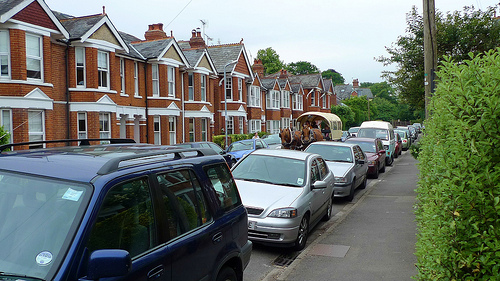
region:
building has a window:
[74, 46, 85, 86]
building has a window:
[95, 50, 107, 88]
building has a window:
[26, 33, 42, 78]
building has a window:
[166, 66, 175, 97]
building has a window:
[186, 70, 193, 100]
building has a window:
[79, 112, 89, 144]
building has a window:
[166, 116, 178, 142]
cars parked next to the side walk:
[3, 120, 437, 279]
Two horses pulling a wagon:
[277, 105, 342, 155]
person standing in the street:
[250, 125, 265, 150]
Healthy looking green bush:
[415, 45, 495, 276]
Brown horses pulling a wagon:
[277, 108, 342, 149]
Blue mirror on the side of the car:
[80, 243, 139, 279]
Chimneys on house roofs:
[131, 20, 211, 72]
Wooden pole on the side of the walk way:
[421, 0, 443, 130]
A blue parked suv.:
[0, 138, 254, 280]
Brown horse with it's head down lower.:
[278, 125, 300, 148]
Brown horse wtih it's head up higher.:
[297, 123, 324, 148]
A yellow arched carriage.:
[292, 111, 342, 143]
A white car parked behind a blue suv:
[226, 147, 336, 251]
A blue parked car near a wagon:
[226, 140, 267, 161]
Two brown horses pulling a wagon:
[277, 123, 323, 150]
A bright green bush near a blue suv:
[420, 55, 499, 278]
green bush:
[451, 85, 488, 210]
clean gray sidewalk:
[371, 193, 391, 262]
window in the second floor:
[70, 48, 91, 93]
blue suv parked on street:
[28, 154, 241, 263]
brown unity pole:
[410, 6, 460, 116]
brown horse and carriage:
[291, 113, 351, 143]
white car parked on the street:
[226, 141, 330, 263]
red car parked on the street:
[344, 133, 388, 171]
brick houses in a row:
[66, 37, 301, 144]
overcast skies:
[276, 8, 375, 60]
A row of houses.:
[7, 1, 358, 132]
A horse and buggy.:
[280, 97, 350, 147]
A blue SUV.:
[5, 130, 251, 275]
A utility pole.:
[407, 1, 457, 101]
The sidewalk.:
[340, 135, 420, 272]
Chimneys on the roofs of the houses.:
[136, 15, 291, 75]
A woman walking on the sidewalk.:
[245, 120, 260, 140]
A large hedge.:
[410, 62, 496, 274]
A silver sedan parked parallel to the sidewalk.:
[225, 142, 336, 239]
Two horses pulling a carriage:
[274, 106, 345, 143]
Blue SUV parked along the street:
[10, 134, 261, 278]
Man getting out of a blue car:
[223, 131, 275, 151]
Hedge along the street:
[422, 49, 494, 274]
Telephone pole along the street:
[418, 0, 443, 129]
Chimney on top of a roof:
[142, 20, 179, 55]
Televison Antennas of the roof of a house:
[200, 18, 216, 46]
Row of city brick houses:
[1, 5, 338, 145]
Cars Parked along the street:
[229, 124, 436, 254]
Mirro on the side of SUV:
[80, 245, 152, 280]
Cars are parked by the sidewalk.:
[59, 125, 399, 208]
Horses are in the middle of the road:
[275, 117, 326, 149]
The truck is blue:
[34, 138, 278, 279]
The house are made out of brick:
[18, 37, 193, 142]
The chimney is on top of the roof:
[190, 27, 209, 51]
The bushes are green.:
[418, 50, 494, 274]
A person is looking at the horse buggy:
[253, 121, 272, 156]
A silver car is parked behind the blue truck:
[236, 145, 354, 233]